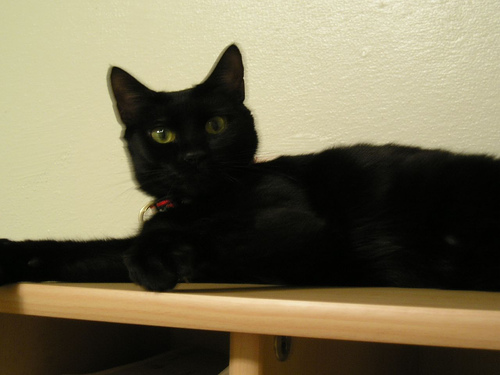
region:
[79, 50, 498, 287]
the cat is black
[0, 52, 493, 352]
the cat is on a shelf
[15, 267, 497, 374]
the shelf is wooden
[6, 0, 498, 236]
the wall is light yellow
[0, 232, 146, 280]
the right paw is outstretched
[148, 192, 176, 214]
the collar is red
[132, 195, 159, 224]
the collar has a metal ring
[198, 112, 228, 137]
the left eye is green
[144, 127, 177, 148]
the right eye is green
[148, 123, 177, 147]
the right eye is glassy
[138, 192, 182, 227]
The cat wears a red collar.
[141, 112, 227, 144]
The cat's eyes are green.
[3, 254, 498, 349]
The cat is lying on a wood table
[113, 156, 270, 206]
The cat's whispers are long.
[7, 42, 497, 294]
The black cat is resting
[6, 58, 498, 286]
The cat is black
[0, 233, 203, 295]
The cat's paws are soft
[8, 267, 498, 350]
The table is made from light colored wood.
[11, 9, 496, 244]
The room's walls are cream colored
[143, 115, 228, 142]
A cat has slit-pupil eyes.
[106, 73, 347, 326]
This is a black cat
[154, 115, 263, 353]
This is a cat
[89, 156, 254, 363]
The cat is laying down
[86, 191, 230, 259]
This is a collar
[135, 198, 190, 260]
The collar is red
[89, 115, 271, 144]
These are two eyes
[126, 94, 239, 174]
The eyes are green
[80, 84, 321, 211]
This is a head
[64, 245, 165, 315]
This is an arm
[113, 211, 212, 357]
This is a paw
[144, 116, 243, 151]
bright green eyes in a face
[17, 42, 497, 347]
a black cat lying on a wooden shelf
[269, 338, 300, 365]
metal shelf support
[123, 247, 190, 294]
a furry black paw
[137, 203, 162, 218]
a brass loop on a collar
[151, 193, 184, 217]
a red and black cloth collar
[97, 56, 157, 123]
a pointy black ear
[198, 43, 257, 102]
a pointy black ear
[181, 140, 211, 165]
a small black nose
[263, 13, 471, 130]
a white stucco wall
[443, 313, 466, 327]
part of a board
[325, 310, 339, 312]
edge of a board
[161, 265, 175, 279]
part of a foot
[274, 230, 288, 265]
edge of a foot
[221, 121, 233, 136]
eye of a cat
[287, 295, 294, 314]
edge of a table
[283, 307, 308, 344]
edge of a wall